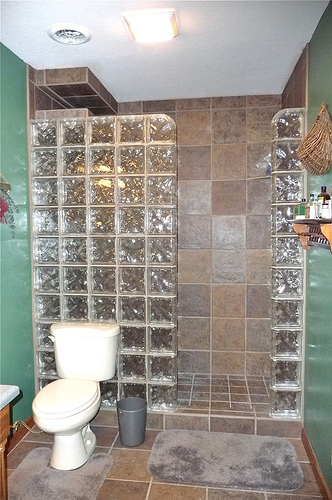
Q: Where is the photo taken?
A: Bathroom.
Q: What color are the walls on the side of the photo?
A: Green.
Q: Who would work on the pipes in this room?
A: Plumber.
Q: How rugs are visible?
A: Two.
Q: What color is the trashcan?
A: Gray.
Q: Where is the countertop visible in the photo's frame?
A: Bottom left corner.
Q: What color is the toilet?
A: White.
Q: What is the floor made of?
A: Tiles.